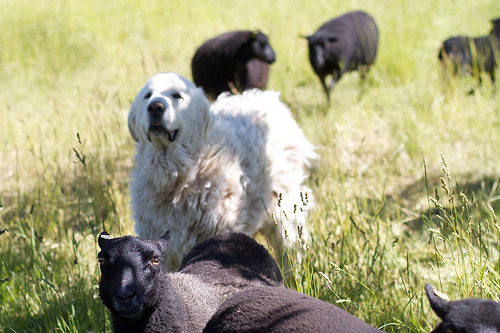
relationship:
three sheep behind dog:
[188, 9, 500, 99] [126, 72, 319, 293]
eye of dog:
[170, 91, 185, 105] [126, 72, 319, 293]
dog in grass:
[126, 72, 319, 293] [1, 0, 500, 332]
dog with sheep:
[126, 72, 319, 293] [189, 28, 276, 91]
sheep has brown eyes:
[96, 233, 499, 327] [96, 249, 165, 267]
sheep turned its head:
[189, 28, 276, 91] [244, 27, 279, 68]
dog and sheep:
[126, 72, 319, 293] [189, 28, 276, 91]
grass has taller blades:
[1, 0, 500, 332] [2, 138, 495, 333]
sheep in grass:
[299, 12, 381, 113] [1, 0, 500, 332]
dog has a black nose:
[126, 72, 319, 293] [146, 97, 169, 125]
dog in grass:
[126, 72, 320, 270] [1, 0, 500, 332]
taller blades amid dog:
[2, 138, 495, 333] [126, 72, 320, 270]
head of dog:
[128, 70, 215, 150] [126, 72, 319, 293]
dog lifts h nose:
[126, 72, 319, 293] [146, 97, 169, 125]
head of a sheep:
[96, 231, 169, 321] [97, 236, 283, 332]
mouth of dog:
[145, 119, 181, 146] [126, 72, 319, 293]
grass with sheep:
[1, 0, 500, 332] [96, 233, 499, 327]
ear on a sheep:
[423, 284, 448, 318] [96, 233, 499, 327]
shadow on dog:
[129, 81, 272, 237] [126, 72, 319, 293]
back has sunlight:
[119, 76, 304, 143] [218, 87, 314, 248]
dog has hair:
[126, 72, 319, 293] [148, 111, 298, 240]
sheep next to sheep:
[97, 236, 283, 332] [96, 233, 499, 327]